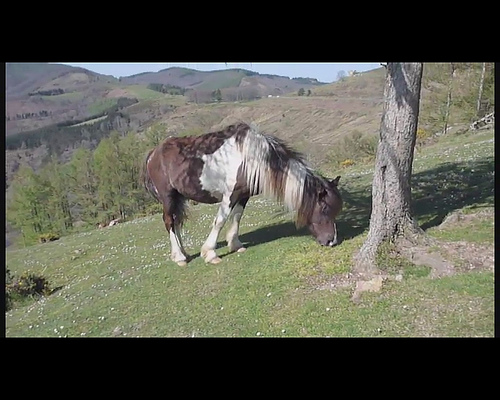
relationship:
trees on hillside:
[147, 83, 188, 96] [43, 86, 187, 112]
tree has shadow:
[352, 61, 431, 270] [338, 157, 497, 242]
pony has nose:
[144, 123, 340, 267] [327, 236, 339, 245]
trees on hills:
[147, 83, 188, 96] [4, 63, 328, 144]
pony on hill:
[144, 123, 340, 267] [8, 129, 498, 342]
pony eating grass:
[144, 123, 340, 267] [1, 133, 499, 339]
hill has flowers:
[8, 129, 498, 342] [101, 236, 154, 285]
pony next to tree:
[144, 123, 340, 267] [352, 61, 431, 270]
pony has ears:
[144, 123, 341, 270] [317, 176, 343, 200]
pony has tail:
[144, 123, 340, 267] [139, 148, 162, 202]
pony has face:
[144, 123, 341, 270] [312, 187, 341, 248]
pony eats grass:
[144, 123, 341, 270] [1, 133, 499, 339]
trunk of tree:
[360, 62, 433, 264] [352, 61, 431, 270]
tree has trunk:
[352, 61, 431, 270] [360, 62, 433, 264]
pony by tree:
[144, 123, 340, 267] [352, 61, 431, 270]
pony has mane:
[144, 123, 340, 267] [244, 124, 328, 232]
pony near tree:
[144, 123, 340, 267] [352, 61, 431, 270]